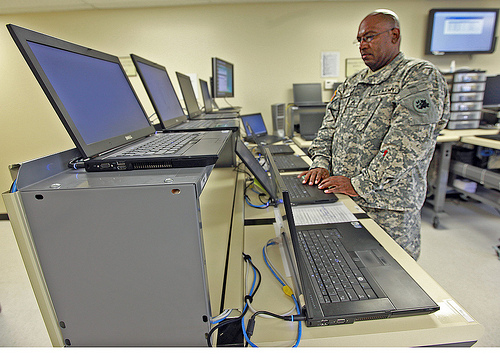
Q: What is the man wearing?
A: A uniform.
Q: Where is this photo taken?
A: In a computer lab.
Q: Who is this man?
A: A soldier.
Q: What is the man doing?
A: Using a computer.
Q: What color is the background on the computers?
A: Blue.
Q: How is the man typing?
A: With his hands.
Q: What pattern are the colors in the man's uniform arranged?
A: Camouflage.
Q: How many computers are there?
A: Ten.